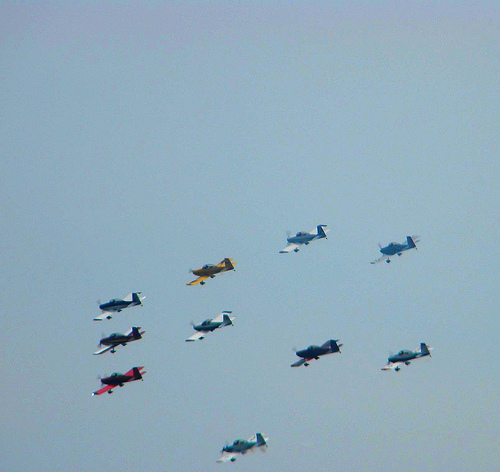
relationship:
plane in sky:
[85, 321, 154, 355] [2, 1, 499, 467]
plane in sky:
[183, 253, 238, 290] [2, 1, 499, 467]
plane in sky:
[183, 253, 238, 290] [24, 22, 478, 213]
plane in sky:
[284, 327, 345, 368] [2, 1, 499, 467]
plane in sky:
[373, 337, 438, 377] [2, 1, 499, 467]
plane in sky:
[274, 213, 347, 256] [2, 1, 499, 467]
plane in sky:
[364, 228, 425, 260] [2, 1, 499, 467]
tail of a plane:
[131, 361, 149, 385] [90, 357, 160, 405]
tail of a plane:
[219, 309, 238, 327] [188, 307, 240, 342]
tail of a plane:
[327, 333, 345, 356] [288, 336, 345, 370]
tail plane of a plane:
[413, 331, 431, 358] [382, 339, 433, 373]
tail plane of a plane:
[245, 418, 270, 450] [211, 429, 270, 469]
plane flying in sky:
[91, 364, 148, 399] [2, 1, 499, 467]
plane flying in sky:
[182, 309, 241, 344] [2, 1, 499, 467]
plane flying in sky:
[183, 253, 238, 290] [2, 1, 499, 467]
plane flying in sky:
[86, 286, 150, 327] [2, 1, 499, 467]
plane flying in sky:
[85, 321, 154, 355] [2, 1, 499, 467]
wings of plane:
[363, 254, 391, 270] [348, 199, 431, 277]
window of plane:
[297, 228, 309, 239] [250, 189, 325, 262]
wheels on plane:
[380, 251, 404, 263] [364, 228, 425, 260]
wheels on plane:
[393, 360, 412, 374] [382, 339, 433, 373]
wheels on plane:
[300, 354, 320, 367] [289, 336, 341, 371]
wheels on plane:
[198, 272, 216, 288] [186, 255, 235, 289]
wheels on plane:
[105, 382, 123, 395] [89, 364, 148, 402]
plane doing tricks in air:
[69, 257, 182, 354] [3, 3, 493, 469]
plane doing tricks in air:
[364, 236, 424, 262] [3, 3, 493, 469]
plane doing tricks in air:
[91, 364, 148, 399] [3, 3, 493, 469]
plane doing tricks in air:
[284, 327, 345, 368] [3, 3, 493, 469]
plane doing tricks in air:
[364, 228, 425, 260] [3, 3, 493, 469]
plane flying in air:
[274, 213, 347, 256] [3, 3, 493, 469]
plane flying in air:
[364, 228, 425, 260] [3, 3, 493, 469]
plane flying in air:
[183, 253, 238, 290] [3, 3, 493, 469]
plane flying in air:
[89, 286, 151, 326] [3, 3, 493, 469]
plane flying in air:
[373, 340, 438, 377] [3, 3, 493, 469]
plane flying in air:
[215, 419, 275, 467] [3, 3, 493, 469]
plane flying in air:
[182, 309, 241, 344] [3, 3, 493, 469]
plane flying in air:
[284, 327, 345, 368] [3, 3, 493, 469]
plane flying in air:
[91, 364, 148, 399] [3, 3, 493, 469]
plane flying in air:
[215, 405, 260, 467] [3, 3, 493, 469]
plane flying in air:
[102, 321, 137, 349] [3, 3, 493, 469]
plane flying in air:
[274, 213, 346, 270] [3, 3, 493, 469]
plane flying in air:
[90, 357, 160, 405] [3, 3, 493, 469]